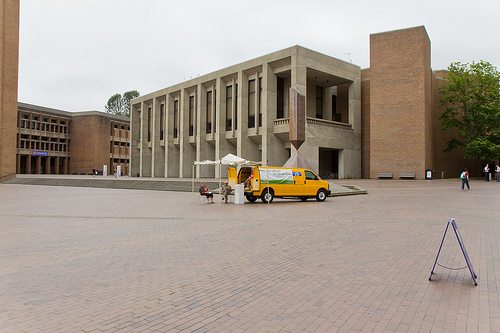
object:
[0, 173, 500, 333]
ground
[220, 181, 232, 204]
man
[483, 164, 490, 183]
man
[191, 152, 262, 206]
canopy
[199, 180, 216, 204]
men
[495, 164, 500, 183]
people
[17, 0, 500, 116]
sky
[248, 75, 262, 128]
long window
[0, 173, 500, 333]
brick walkway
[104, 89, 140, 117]
tree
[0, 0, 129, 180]
building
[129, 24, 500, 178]
building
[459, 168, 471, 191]
people walking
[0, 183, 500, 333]
bricks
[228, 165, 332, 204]
large van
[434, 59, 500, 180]
tree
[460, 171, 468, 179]
backpack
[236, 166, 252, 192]
back doors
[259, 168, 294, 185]
sign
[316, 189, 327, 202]
tire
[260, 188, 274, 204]
tire